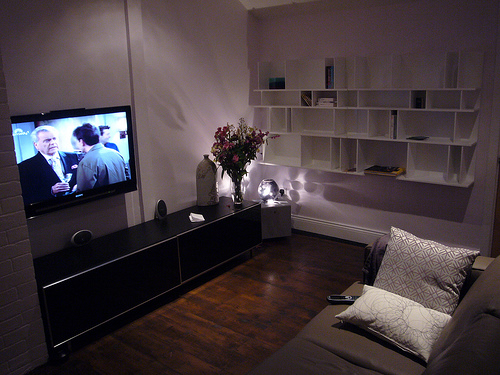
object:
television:
[10, 105, 138, 218]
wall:
[1, 0, 248, 260]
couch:
[244, 229, 499, 375]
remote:
[326, 295, 362, 305]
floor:
[28, 229, 367, 374]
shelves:
[249, 87, 333, 93]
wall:
[247, 1, 499, 257]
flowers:
[231, 153, 242, 162]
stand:
[35, 193, 262, 362]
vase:
[231, 170, 245, 205]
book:
[407, 136, 427, 141]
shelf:
[400, 133, 452, 145]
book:
[364, 164, 403, 177]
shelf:
[357, 163, 405, 181]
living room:
[1, 0, 497, 373]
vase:
[257, 177, 280, 206]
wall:
[0, 57, 50, 374]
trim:
[124, 0, 159, 222]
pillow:
[335, 283, 453, 365]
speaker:
[71, 230, 94, 248]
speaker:
[157, 199, 168, 219]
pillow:
[372, 222, 479, 317]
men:
[72, 124, 131, 196]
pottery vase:
[195, 154, 219, 207]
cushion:
[297, 278, 428, 374]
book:
[188, 212, 205, 222]